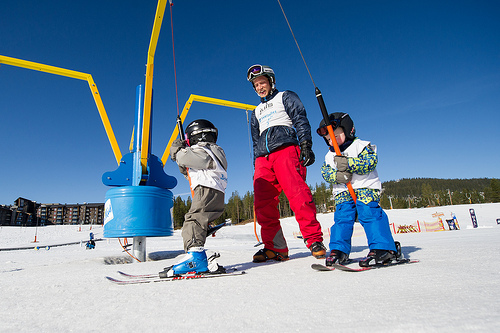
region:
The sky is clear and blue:
[338, 20, 486, 97]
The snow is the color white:
[26, 288, 475, 330]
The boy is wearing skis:
[310, 240, 415, 275]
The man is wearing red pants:
[248, 145, 335, 253]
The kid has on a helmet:
[311, 100, 361, 152]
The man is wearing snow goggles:
[240, 58, 277, 83]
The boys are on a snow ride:
[102, 18, 422, 301]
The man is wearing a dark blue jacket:
[243, 88, 314, 164]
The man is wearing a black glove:
[293, 140, 318, 170]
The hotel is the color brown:
[2, 190, 104, 228]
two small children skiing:
[103, 109, 417, 281]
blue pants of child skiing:
[320, 194, 387, 259]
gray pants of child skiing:
[170, 192, 229, 242]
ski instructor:
[237, 59, 327, 263]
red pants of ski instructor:
[250, 152, 318, 253]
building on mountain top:
[12, 191, 120, 222]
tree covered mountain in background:
[325, 169, 493, 201]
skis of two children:
[102, 251, 424, 280]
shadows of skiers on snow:
[224, 232, 426, 277]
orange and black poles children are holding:
[175, 95, 355, 205]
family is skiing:
[105, 64, 419, 284]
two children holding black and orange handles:
[175, 87, 357, 208]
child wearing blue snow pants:
[329, 199, 398, 253]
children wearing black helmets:
[185, 110, 356, 148]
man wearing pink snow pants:
[252, 143, 324, 251]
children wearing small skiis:
[105, 258, 410, 283]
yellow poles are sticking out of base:
[0, 0, 256, 181]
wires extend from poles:
[167, 0, 357, 242]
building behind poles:
[0, 195, 105, 225]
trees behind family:
[172, 175, 498, 230]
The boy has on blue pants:
[323, 188, 398, 256]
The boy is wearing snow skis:
[308, 245, 421, 276]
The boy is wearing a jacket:
[318, 135, 384, 201]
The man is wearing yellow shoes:
[248, 241, 330, 263]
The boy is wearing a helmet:
[180, 115, 228, 145]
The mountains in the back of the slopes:
[395, 176, 497, 208]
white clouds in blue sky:
[9, 13, 50, 36]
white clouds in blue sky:
[19, 94, 54, 111]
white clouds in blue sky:
[17, 103, 79, 133]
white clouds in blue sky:
[13, 141, 67, 171]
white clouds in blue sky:
[179, 30, 231, 56]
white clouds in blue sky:
[418, 9, 473, 64]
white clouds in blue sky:
[323, 30, 379, 75]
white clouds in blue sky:
[411, 109, 479, 147]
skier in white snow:
[230, 56, 320, 268]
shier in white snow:
[309, 96, 396, 273]